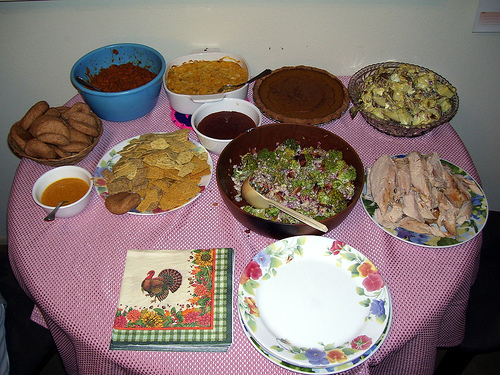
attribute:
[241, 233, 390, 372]
plate — white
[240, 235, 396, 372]
plates — white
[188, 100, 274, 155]
bowl — in used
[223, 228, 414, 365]
plates — couple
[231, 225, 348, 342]
plates — white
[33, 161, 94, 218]
cup — white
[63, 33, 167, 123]
bowl — blue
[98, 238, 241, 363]
napkins — set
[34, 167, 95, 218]
bowl — condiment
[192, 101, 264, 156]
bowl — condiment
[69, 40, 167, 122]
bowl — blue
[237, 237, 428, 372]
plates — white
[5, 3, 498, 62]
wall — white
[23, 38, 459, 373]
cloth — red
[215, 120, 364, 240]
bowl — burgundy, large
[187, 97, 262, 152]
bowl — full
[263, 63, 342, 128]
pie — pumpkin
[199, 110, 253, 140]
liquid — brown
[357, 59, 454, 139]
vegetables — brown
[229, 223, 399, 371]
plates — in pile, white